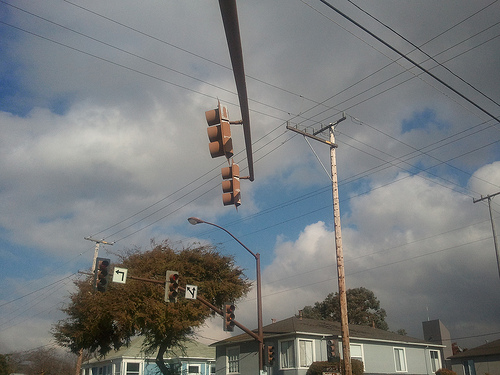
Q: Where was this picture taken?
A: At an intersection.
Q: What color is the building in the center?
A: Gray.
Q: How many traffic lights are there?
A: Seven.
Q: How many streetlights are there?
A: One.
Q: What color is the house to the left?
A: Blue.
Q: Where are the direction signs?
A: On the light pole.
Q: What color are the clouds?
A: Gray.